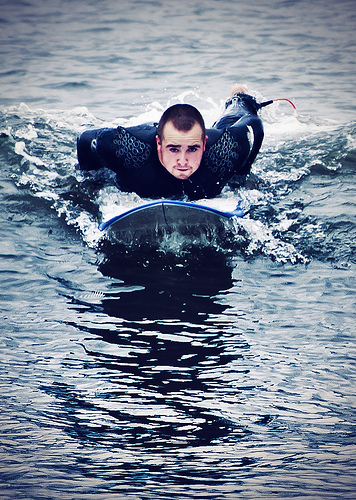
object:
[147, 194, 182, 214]
tip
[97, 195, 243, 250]
surfboard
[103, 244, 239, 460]
shadow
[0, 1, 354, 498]
water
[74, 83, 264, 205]
man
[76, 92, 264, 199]
wetsuit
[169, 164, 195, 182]
beard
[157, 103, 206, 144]
hair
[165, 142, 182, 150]
brow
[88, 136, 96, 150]
logo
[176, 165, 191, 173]
mouth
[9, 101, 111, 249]
wave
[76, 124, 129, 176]
arm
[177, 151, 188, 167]
nose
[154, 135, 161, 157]
ear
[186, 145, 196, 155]
eye